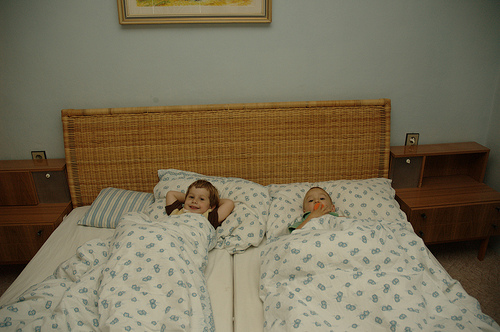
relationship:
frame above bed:
[117, 0, 274, 26] [32, 72, 387, 328]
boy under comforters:
[165, 179, 235, 230] [108, 191, 387, 321]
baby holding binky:
[288, 187, 348, 234] [314, 203, 329, 214]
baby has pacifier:
[288, 187, 348, 234] [311, 201, 328, 211]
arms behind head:
[154, 186, 239, 215] [181, 177, 213, 211]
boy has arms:
[165, 179, 235, 230] [154, 186, 239, 215]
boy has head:
[165, 179, 235, 230] [181, 177, 213, 211]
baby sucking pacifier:
[288, 187, 348, 234] [313, 199, 323, 212]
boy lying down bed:
[164, 180, 237, 226] [1, 97, 494, 330]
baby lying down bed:
[288, 187, 348, 234] [1, 97, 494, 330]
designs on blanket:
[122, 259, 175, 304] [0, 210, 496, 330]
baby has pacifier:
[286, 184, 343, 232] [313, 200, 326, 212]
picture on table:
[405, 134, 421, 151] [393, 140, 493, 261]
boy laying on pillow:
[165, 179, 235, 230] [155, 164, 267, 244]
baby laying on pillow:
[288, 187, 348, 234] [261, 174, 418, 243]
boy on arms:
[165, 179, 235, 230] [164, 190, 232, 212]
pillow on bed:
[86, 190, 163, 233] [55, 100, 421, 330]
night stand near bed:
[0, 157, 72, 266] [35, 83, 415, 330]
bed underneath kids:
[55, 100, 421, 330] [166, 174, 358, 211]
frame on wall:
[117, 0, 274, 26] [26, 5, 463, 96]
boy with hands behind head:
[165, 179, 235, 230] [177, 175, 208, 208]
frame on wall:
[115, 2, 279, 24] [61, 32, 328, 80]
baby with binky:
[288, 187, 348, 234] [312, 201, 331, 215]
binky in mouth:
[312, 201, 331, 215] [314, 200, 328, 217]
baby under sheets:
[288, 187, 348, 234] [276, 211, 417, 325]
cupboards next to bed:
[407, 120, 497, 262] [55, 100, 421, 330]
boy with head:
[165, 179, 235, 230] [188, 181, 207, 201]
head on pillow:
[188, 181, 207, 201] [168, 168, 262, 241]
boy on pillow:
[165, 179, 235, 230] [234, 179, 290, 237]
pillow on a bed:
[265, 168, 408, 241] [7, 100, 451, 325]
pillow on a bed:
[147, 160, 272, 254] [7, 100, 451, 325]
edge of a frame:
[122, 20, 277, 30] [117, 0, 274, 26]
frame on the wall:
[117, 0, 274, 26] [13, 20, 471, 172]